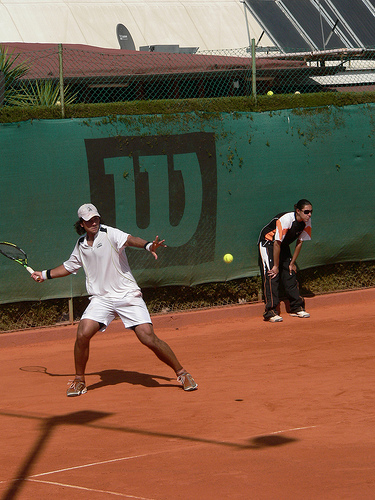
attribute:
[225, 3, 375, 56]
panel — gray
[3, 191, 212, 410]
man — stretching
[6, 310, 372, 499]
court — painted, clay, red, brown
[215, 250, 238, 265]
ball — moving, round, yellow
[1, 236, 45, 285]
racket — green, black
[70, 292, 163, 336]
shorts — white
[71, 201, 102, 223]
cap — white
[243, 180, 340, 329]
person — standing, bending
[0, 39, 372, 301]
fence — mesh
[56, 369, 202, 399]
shoes — orange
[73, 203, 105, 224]
hat — white